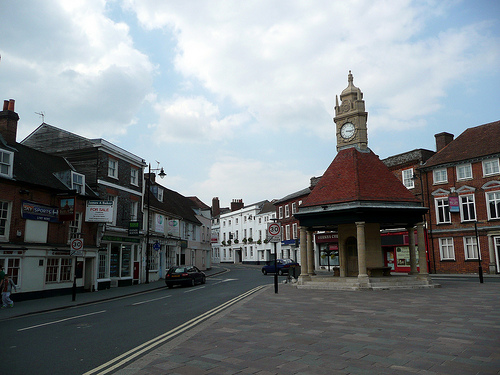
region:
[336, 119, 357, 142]
White clock in top of tower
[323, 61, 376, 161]
Small tower on roof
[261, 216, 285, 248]
Street sign is white.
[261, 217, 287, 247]
Street sign has a red circle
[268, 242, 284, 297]
Pole of sign is black.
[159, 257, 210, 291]
Car parked on left side of street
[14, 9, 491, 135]
Sky is full of clouds.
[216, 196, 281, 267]
White building at the end of street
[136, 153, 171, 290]
Light pole on left side.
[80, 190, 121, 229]
Board on building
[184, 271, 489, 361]
city square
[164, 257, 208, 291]
dark car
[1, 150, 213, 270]
two and three story buildings with no space between them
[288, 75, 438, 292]
clock tower structure in town square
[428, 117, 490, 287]
colonial brick building with white windows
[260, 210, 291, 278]
no parking sign on street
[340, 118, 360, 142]
clock on clock tower in square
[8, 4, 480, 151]
partially cloudy blue sky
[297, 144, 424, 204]
red roof on clock tower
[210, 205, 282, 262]
white colonial building with windows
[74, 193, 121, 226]
A for sale sign displayed on the building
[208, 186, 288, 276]
A white building among the brick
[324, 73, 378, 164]
A clock sits on top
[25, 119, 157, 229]
Weathered wooden siding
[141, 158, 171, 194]
A street light as tall as a three story building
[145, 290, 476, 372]
A square covered in paving stones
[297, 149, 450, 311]
A covered rest area with a bench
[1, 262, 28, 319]
A man walks along the road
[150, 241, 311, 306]
Two cars meet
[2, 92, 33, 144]
A chimney with two red pipes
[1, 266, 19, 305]
man walking at the side walk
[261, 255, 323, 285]
the car is blue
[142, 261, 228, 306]
the car is parked at the side walk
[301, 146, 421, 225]
the roof is red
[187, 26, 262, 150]
the clouds are white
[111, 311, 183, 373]
the line is white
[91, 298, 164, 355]
the ground is gray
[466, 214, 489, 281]
the pole is black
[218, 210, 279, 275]
the building is white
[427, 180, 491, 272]
window panes are white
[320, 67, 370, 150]
clock on top of building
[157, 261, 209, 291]
car on left side of road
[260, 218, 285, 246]
white sign with red circle and black letters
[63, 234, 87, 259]
white sign with red circle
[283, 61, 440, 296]
gazebo with clock on top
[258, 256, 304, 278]
car turning onto road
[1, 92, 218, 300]
group of buildings built close to each other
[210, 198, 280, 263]
white buildings in center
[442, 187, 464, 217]
sign on side of building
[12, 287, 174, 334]
white lines on road